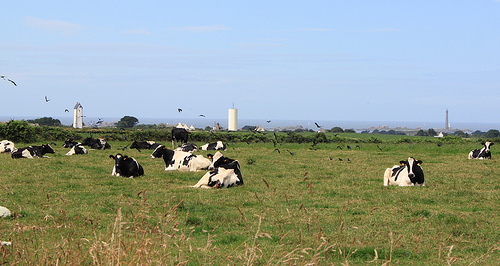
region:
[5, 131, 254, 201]
this is a herd of cattle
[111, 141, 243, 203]
the cows are sitted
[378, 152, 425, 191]
the cow is white and black in color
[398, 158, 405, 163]
this is the ear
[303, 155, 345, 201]
the grass is green in color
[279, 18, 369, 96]
the sky is blue in color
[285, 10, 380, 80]
the sky is clear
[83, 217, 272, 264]
the grass are dry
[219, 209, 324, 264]
the grass are brown in color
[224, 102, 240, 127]
this is a tower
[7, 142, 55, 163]
a black and white cow sitting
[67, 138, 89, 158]
a black and white cow sitting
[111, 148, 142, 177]
a black and white cow sitting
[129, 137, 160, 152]
a black and white cow sitting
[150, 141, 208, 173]
a black and white cow sitting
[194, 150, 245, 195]
a black and white cow sitting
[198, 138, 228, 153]
a black and white cow sitting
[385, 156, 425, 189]
a black and white cow sitting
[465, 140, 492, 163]
a black and white cow sitting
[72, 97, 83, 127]
a tall white building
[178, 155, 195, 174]
the cow is black and white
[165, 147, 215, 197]
the cow is black and white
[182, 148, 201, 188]
the cow is black and white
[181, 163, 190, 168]
the cow is black and white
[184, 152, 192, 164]
the cow is black and white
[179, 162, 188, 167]
the cow is black and white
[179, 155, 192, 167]
the cow is black and white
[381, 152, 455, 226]
a cow is sitting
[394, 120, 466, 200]
a cow is sitting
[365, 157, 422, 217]
a cow is sitting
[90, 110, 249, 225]
cows in the grass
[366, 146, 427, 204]
black and white animal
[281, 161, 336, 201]
grass under the cows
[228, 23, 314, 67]
blue sky above land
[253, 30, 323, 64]
sky with no clouds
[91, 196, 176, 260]
brown grass in the foreground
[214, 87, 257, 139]
white object in the background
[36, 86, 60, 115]
bird flying in the air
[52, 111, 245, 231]
many cows laying down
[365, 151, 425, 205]
cow laying by itself